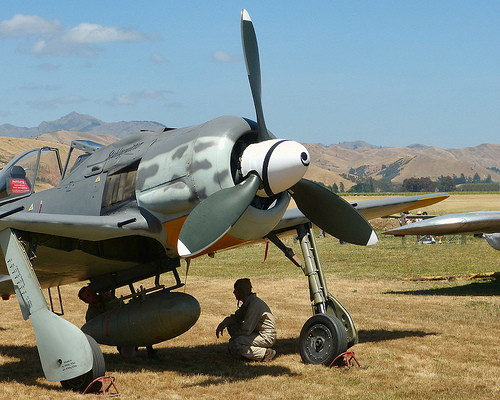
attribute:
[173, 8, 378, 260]
propellor — black, white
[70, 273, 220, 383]
bomb — silver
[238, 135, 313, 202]
plane nose — white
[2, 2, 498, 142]
sky — blue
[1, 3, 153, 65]
clouds — white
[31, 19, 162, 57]
cloud — white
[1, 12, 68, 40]
cloud — white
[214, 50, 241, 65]
clouds — white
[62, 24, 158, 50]
clouds — white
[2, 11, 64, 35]
clouds — white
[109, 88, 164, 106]
clouds — white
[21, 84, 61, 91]
clouds — white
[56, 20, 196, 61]
clouds — white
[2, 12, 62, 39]
cloud — white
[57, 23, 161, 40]
cloud — white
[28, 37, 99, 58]
cloud — white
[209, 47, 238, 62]
cloud — white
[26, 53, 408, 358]
plane — grey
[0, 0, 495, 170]
sky — blue, white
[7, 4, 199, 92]
cloud — white, fluffy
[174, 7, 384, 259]
propeller — black, white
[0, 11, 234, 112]
clouds — white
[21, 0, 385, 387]
plane — gray 